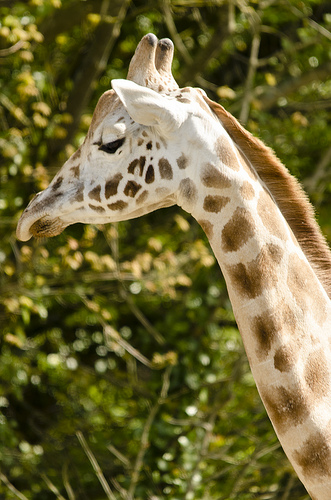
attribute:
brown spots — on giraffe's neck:
[199, 158, 292, 295]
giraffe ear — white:
[110, 75, 191, 135]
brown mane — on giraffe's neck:
[201, 92, 319, 234]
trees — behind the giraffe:
[1, 0, 221, 447]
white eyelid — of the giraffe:
[97, 121, 125, 140]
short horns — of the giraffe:
[124, 33, 183, 93]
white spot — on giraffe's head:
[173, 104, 209, 144]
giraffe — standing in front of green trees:
[11, 31, 318, 492]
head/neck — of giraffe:
[4, 30, 321, 385]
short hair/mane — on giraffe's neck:
[208, 94, 318, 245]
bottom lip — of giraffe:
[35, 219, 60, 237]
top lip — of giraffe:
[16, 197, 44, 243]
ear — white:
[102, 69, 180, 132]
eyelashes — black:
[95, 141, 130, 153]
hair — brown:
[230, 113, 316, 274]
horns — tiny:
[94, 25, 180, 75]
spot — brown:
[270, 351, 302, 373]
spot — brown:
[248, 365, 319, 423]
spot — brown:
[196, 189, 236, 218]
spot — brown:
[253, 179, 287, 257]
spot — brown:
[222, 177, 250, 213]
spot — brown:
[211, 216, 287, 280]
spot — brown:
[40, 169, 65, 192]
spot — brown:
[137, 139, 158, 154]